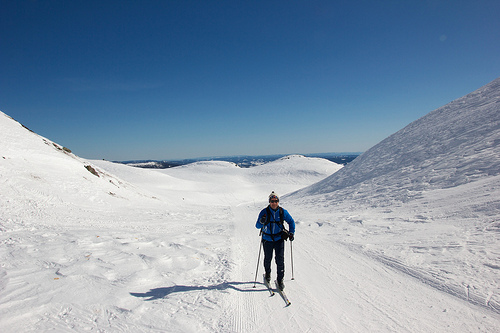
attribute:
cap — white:
[266, 188, 281, 200]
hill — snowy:
[1, 107, 126, 231]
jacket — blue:
[254, 206, 296, 244]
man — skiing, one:
[255, 189, 297, 293]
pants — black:
[260, 238, 287, 283]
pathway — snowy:
[213, 172, 325, 325]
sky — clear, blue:
[0, 1, 499, 163]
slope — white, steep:
[273, 73, 499, 317]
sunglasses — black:
[268, 196, 280, 204]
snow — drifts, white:
[1, 76, 500, 326]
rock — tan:
[83, 160, 104, 180]